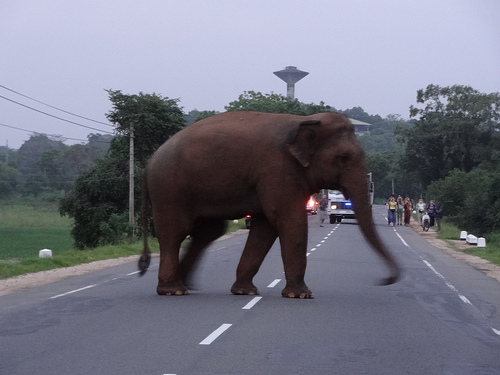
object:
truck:
[342, 168, 403, 286]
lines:
[192, 220, 354, 344]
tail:
[135, 177, 153, 275]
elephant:
[133, 108, 403, 298]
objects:
[457, 227, 484, 247]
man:
[313, 189, 330, 225]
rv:
[323, 165, 376, 224]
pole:
[124, 95, 140, 234]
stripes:
[195, 222, 351, 345]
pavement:
[7, 200, 483, 369]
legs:
[155, 210, 314, 296]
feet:
[156, 283, 188, 296]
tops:
[222, 89, 337, 114]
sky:
[3, 2, 484, 152]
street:
[5, 199, 484, 369]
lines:
[185, 270, 290, 360]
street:
[52, 193, 473, 349]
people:
[382, 191, 440, 231]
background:
[62, 61, 451, 196]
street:
[207, 219, 452, 355]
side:
[417, 224, 486, 292]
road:
[310, 228, 467, 373]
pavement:
[75, 309, 328, 372]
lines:
[6, 87, 122, 145]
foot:
[281, 269, 320, 311]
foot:
[230, 276, 260, 300]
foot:
[179, 274, 201, 290]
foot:
[148, 278, 192, 301]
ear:
[283, 119, 317, 169]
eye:
[327, 154, 354, 170]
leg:
[281, 215, 311, 301]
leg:
[234, 229, 271, 299]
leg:
[153, 233, 180, 295]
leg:
[184, 229, 222, 291]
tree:
[405, 86, 498, 190]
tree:
[426, 169, 498, 240]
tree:
[59, 165, 145, 253]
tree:
[106, 89, 186, 159]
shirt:
[389, 202, 396, 209]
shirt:
[403, 201, 410, 211]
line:
[197, 320, 227, 343]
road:
[0, 206, 500, 371]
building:
[274, 64, 309, 101]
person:
[399, 198, 413, 229]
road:
[384, 222, 454, 267]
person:
[384, 193, 398, 223]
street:
[377, 216, 432, 244]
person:
[413, 193, 425, 222]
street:
[384, 207, 447, 239]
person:
[401, 194, 415, 226]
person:
[426, 196, 438, 230]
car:
[319, 189, 359, 227]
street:
[313, 220, 367, 267]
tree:
[55, 84, 180, 262]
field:
[2, 200, 143, 278]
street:
[41, 242, 473, 354]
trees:
[62, 137, 144, 246]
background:
[10, 73, 499, 103]